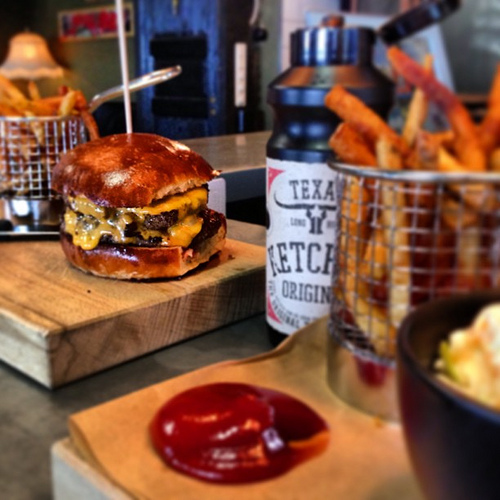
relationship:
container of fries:
[326, 160, 497, 419] [326, 44, 497, 356]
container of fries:
[326, 160, 497, 419] [1, 72, 98, 197]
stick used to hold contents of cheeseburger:
[111, 4, 137, 136] [49, 132, 228, 282]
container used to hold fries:
[326, 160, 497, 419] [323, 44, 498, 172]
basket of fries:
[3, 112, 80, 229] [2, 76, 92, 121]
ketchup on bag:
[142, 370, 332, 484] [64, 318, 425, 497]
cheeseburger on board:
[49, 132, 228, 282] [1, 200, 283, 390]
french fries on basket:
[321, 47, 498, 175] [323, 151, 498, 426]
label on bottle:
[263, 152, 343, 336] [267, 14, 393, 332]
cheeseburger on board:
[47, 128, 230, 283] [1, 200, 268, 390]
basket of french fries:
[0, 112, 89, 236] [1, 76, 103, 148]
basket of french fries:
[323, 151, 498, 426] [321, 47, 498, 175]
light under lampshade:
[22, 44, 35, 55] [1, 30, 66, 80]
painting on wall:
[56, 5, 136, 39] [2, 2, 499, 117]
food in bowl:
[426, 292, 499, 404] [398, 289, 498, 496]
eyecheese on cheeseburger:
[64, 189, 207, 247] [49, 132, 228, 282]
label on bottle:
[263, 152, 340, 335] [261, 24, 394, 345]